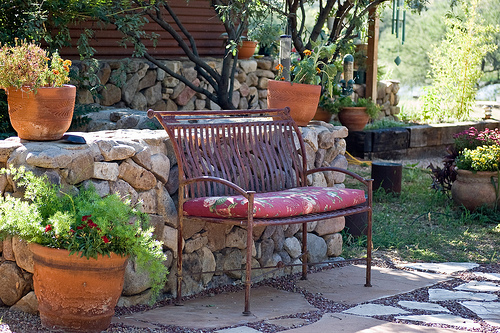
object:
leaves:
[477, 21, 498, 35]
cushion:
[183, 186, 367, 219]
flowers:
[452, 127, 500, 145]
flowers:
[275, 49, 321, 80]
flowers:
[0, 37, 73, 86]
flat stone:
[295, 264, 455, 305]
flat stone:
[110, 286, 318, 329]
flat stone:
[397, 300, 450, 313]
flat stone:
[428, 288, 498, 303]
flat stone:
[279, 311, 464, 333]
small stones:
[1, 309, 39, 332]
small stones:
[111, 260, 498, 333]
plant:
[265, 38, 338, 99]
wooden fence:
[346, 121, 500, 160]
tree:
[0, 0, 500, 121]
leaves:
[1, 0, 160, 90]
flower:
[303, 49, 311, 56]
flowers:
[45, 214, 109, 243]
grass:
[342, 167, 500, 270]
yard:
[0, 53, 500, 333]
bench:
[146, 106, 376, 316]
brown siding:
[37, 0, 247, 59]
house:
[8, 0, 229, 60]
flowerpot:
[6, 83, 76, 140]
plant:
[426, 127, 500, 195]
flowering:
[0, 165, 170, 309]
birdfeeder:
[279, 35, 292, 82]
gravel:
[50, 127, 166, 233]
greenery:
[0, 43, 72, 99]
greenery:
[291, 38, 338, 99]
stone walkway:
[110, 262, 498, 333]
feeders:
[267, 79, 322, 127]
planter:
[451, 166, 500, 212]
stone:
[117, 157, 156, 192]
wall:
[88, 71, 184, 110]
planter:
[26, 242, 130, 333]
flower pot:
[237, 41, 257, 61]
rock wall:
[71, 56, 278, 114]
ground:
[2, 156, 497, 333]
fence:
[0, 121, 349, 313]